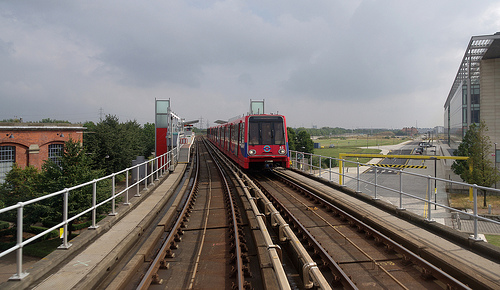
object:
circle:
[264, 145, 271, 152]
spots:
[271, 156, 276, 158]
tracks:
[201, 136, 363, 289]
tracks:
[199, 135, 247, 289]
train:
[205, 114, 292, 173]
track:
[137, 135, 200, 289]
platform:
[176, 132, 195, 164]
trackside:
[21, 132, 196, 289]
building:
[0, 125, 90, 195]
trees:
[104, 119, 155, 176]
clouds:
[90, 15, 287, 91]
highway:
[347, 138, 453, 229]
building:
[443, 33, 500, 192]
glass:
[447, 83, 464, 158]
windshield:
[249, 119, 285, 145]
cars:
[419, 143, 431, 148]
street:
[346, 139, 451, 230]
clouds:
[0, 9, 109, 76]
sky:
[0, 0, 499, 130]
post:
[366, 164, 427, 170]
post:
[63, 188, 68, 246]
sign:
[59, 228, 64, 239]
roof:
[0, 125, 89, 130]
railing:
[0, 146, 180, 283]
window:
[247, 117, 284, 144]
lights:
[249, 149, 257, 155]